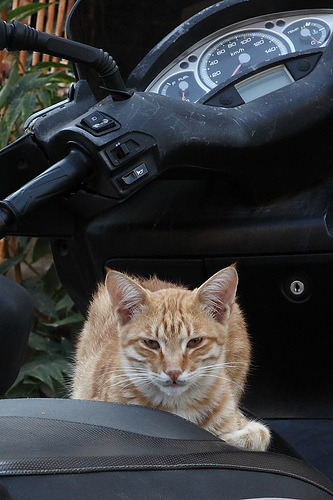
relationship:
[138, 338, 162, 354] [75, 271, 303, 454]
eye of cat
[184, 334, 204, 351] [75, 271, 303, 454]
eye of cat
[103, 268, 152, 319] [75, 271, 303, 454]
ear of cat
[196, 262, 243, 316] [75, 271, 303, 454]
ear of cat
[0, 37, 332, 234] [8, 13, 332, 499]
handle bar of motorcycle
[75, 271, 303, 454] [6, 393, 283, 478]
cat sitting on seat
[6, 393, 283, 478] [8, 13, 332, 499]
seat of motorcycle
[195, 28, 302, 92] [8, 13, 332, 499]
speedometer on motorcycle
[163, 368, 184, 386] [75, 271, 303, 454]
nose of cat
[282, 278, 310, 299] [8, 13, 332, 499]
key hole on motorcycle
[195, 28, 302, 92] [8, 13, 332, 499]
speedometer of bike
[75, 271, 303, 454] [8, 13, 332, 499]
cat sitting in bike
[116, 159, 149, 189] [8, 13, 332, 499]
horn button in motorcycle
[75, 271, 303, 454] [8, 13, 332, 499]
cat sitting in motorcycle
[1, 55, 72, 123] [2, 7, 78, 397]
leaves and plant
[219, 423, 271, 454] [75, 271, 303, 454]
paw of cat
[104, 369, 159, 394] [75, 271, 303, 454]
whiskers of cat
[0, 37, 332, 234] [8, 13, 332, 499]
handle bar on bike